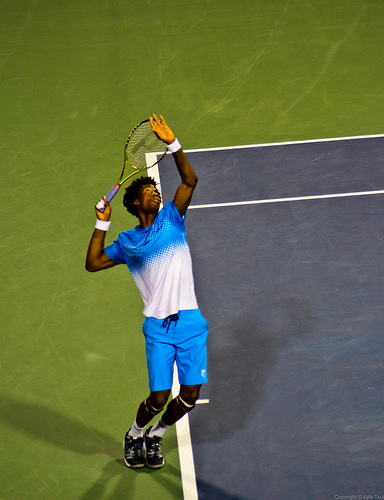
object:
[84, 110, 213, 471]
man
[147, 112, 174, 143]
hand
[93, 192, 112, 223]
hand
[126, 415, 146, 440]
sock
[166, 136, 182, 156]
band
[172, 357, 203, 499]
white line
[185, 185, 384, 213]
line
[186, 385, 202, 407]
knee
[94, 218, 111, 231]
band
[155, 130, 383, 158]
scuff mark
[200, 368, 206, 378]
symbol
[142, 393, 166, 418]
knee pads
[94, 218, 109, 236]
wrist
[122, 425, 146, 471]
shoes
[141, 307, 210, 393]
shorts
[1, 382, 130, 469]
shadow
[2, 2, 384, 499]
ground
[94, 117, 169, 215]
racket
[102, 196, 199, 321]
shirt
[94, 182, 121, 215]
handle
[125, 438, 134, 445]
symbol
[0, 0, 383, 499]
tennis court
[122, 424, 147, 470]
feet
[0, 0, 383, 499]
surface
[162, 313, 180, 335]
strings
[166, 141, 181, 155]
wrist